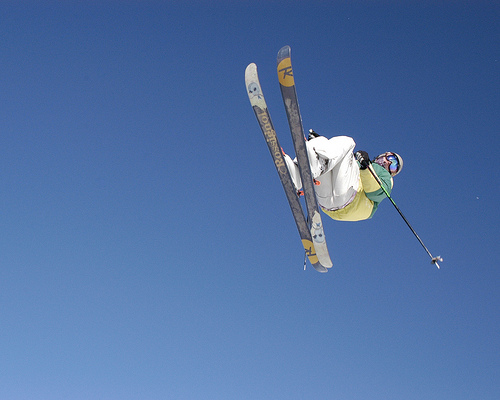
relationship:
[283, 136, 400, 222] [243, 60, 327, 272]
alien on ski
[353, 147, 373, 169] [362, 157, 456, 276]
hand on ski pole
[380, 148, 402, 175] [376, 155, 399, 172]
goggles on face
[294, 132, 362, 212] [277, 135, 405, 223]
pants on skier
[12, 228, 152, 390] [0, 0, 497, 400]
cloud in blue sky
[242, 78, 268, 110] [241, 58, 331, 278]
alien on ski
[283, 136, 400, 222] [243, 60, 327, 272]
alien jumping on ski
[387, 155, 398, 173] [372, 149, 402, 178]
goggles on face